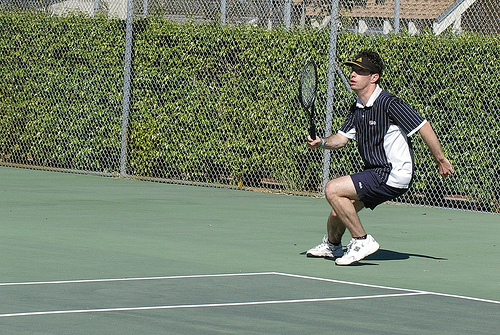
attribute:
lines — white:
[6, 258, 496, 333]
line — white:
[2, 270, 279, 286]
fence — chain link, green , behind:
[0, 0, 499, 216]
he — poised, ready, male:
[296, 48, 451, 263]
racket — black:
[299, 60, 321, 137]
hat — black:
[345, 48, 388, 73]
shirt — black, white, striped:
[343, 90, 430, 190]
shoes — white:
[307, 237, 382, 266]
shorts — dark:
[349, 170, 402, 213]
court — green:
[5, 163, 499, 333]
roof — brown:
[292, 2, 460, 25]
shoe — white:
[336, 237, 380, 266]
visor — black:
[342, 57, 379, 74]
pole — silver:
[118, 1, 139, 176]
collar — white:
[354, 86, 384, 113]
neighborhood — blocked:
[30, 2, 497, 43]